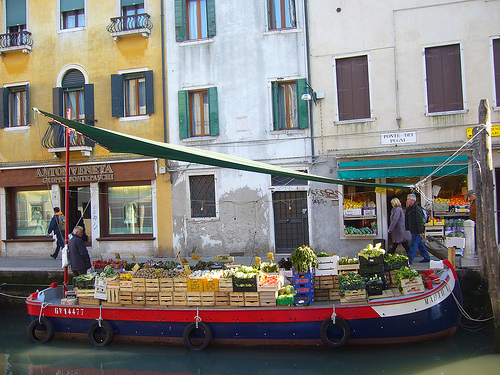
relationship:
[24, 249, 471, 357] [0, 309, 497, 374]
boat floats in river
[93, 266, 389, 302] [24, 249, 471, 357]
food sits on boat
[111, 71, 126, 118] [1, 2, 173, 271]
shutter on building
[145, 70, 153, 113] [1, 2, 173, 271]
shutter on building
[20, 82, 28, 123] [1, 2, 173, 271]
shutter on building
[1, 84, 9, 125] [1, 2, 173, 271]
shutter on building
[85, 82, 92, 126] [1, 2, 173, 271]
shutter on building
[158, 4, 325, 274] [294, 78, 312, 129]
building has window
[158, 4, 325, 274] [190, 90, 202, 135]
building has window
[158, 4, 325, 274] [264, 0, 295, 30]
building has shutter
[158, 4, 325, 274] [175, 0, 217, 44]
building has shutter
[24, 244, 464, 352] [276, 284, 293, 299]
boat of produce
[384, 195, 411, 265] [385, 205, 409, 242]
woman wears grey coat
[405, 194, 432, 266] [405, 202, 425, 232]
man wears jacket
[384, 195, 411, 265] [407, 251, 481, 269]
woman walks along dock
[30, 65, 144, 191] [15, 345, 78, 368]
window faces onto water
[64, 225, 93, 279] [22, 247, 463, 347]
man on boat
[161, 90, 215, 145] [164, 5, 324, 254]
window on front of building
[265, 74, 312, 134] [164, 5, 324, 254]
window on front of building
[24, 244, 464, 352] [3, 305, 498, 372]
boat in river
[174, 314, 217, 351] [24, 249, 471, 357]
tire attached to boat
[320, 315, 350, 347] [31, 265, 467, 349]
tire attached to boat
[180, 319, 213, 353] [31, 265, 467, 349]
tire attached to boat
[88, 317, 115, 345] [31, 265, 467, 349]
tire attached to boat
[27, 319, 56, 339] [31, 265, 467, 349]
tire attached to boat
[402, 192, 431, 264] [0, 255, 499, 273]
man walking on road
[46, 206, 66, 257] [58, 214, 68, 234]
man wearing backpack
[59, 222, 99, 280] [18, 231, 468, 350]
man near boat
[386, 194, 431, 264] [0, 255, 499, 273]
couple walking on road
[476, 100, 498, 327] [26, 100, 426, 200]
pole tied to tarp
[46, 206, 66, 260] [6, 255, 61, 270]
man near road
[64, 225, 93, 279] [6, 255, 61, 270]
man near road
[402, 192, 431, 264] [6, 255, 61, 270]
man near road